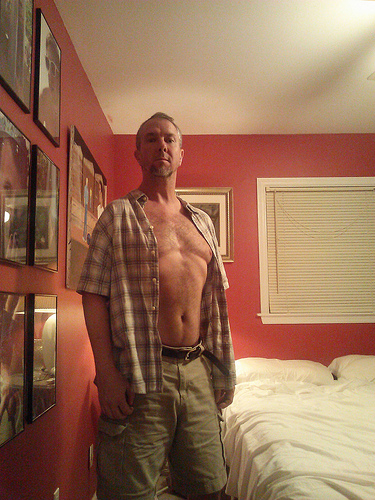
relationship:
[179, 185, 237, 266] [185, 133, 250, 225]
frame on wall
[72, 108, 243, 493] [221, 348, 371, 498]
man on bed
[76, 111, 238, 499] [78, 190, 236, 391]
man wearing unbuttoned shirt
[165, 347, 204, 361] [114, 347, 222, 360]
belt around waist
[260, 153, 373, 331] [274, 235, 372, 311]
windowframe with blinds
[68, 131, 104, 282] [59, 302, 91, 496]
frame on wall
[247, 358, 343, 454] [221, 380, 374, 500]
part of  a bed sheets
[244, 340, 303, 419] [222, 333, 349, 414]
part of  a pillow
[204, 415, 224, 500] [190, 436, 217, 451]
part of  a line